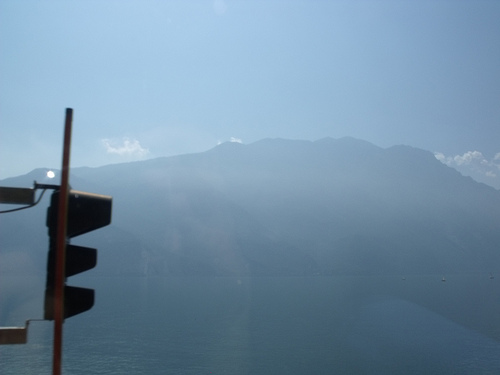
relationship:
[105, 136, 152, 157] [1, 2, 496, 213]
cloud in sky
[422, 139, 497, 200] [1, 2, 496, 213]
cloud in sky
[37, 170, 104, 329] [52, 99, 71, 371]
light on pole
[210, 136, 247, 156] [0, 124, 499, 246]
hill on mountain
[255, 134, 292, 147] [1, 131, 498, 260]
hill on mountain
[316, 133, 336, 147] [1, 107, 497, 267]
hill on mountain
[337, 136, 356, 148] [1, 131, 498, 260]
hill on mountain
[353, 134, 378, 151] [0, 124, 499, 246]
hill on mountain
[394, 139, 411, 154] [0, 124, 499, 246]
hill on mountain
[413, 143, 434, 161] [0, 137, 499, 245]
hill on mountain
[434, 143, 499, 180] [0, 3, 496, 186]
cloud in sky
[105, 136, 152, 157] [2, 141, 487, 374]
cloud are by mountain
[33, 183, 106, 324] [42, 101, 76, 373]
street light in pole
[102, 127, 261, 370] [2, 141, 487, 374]
sunlight hitting mountain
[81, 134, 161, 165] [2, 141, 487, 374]
cloud behind mountain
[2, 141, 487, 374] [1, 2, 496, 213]
mountain in sky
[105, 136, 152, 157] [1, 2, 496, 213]
cloud are in sky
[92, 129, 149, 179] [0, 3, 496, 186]
cloud in sky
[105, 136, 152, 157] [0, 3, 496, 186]
cloud are in sky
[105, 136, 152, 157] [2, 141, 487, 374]
cloud are behind mountain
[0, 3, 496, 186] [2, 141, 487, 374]
sky above mountain